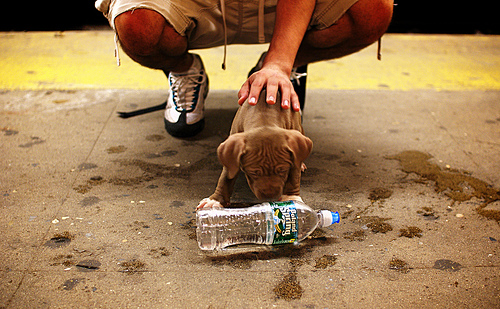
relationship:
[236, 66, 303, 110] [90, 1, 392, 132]
hand of man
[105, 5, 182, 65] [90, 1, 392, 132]
knee of man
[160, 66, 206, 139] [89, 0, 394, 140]
shoe of young man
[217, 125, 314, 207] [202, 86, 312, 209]
head of puppy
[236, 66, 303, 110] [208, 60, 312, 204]
hand touching dog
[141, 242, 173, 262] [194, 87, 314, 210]
print from dog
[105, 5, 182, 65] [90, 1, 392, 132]
knee of squating man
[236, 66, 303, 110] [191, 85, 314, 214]
hand touching puppy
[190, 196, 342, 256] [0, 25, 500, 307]
bottle on sidewalk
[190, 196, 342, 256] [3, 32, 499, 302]
bottle on ground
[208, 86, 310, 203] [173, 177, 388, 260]
puppy behind bottle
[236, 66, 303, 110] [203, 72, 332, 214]
hand holding puppy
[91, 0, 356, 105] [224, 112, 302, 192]
person squatting behind puppy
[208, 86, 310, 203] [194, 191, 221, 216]
puppy has paw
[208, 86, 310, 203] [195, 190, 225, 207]
puppy has paw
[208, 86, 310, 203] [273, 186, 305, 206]
puppy has paw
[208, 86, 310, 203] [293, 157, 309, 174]
puppy has paw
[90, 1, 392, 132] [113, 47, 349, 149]
man wearing shoes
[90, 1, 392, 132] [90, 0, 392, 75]
man wearing shorts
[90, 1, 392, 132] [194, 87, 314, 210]
man holding dog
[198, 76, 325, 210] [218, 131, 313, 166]
dog has ears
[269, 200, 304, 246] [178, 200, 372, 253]
label on bottle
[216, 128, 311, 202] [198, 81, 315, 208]
face of puppy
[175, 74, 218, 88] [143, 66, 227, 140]
slaces on a shoe